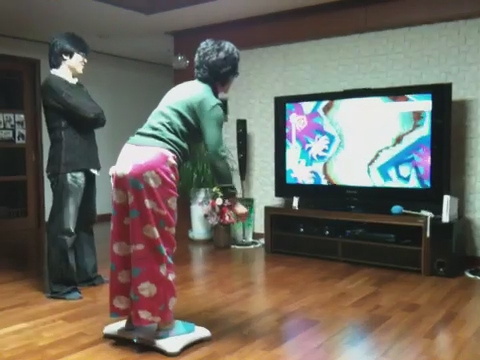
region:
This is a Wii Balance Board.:
[99, 307, 218, 357]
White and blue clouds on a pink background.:
[144, 221, 176, 263]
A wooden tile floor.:
[276, 297, 411, 347]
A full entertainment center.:
[260, 201, 443, 275]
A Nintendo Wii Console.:
[440, 192, 459, 225]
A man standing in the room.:
[36, 24, 107, 305]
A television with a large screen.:
[268, 88, 456, 207]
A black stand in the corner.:
[228, 118, 258, 188]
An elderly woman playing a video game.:
[94, 28, 255, 357]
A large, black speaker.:
[430, 214, 458, 275]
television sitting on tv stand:
[267, 75, 457, 308]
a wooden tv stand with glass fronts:
[265, 199, 433, 271]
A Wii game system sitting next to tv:
[414, 181, 464, 233]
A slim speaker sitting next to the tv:
[232, 112, 262, 227]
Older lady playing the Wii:
[105, 35, 253, 353]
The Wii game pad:
[81, 309, 217, 359]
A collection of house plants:
[195, 160, 264, 270]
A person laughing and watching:
[39, 36, 103, 321]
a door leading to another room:
[1, 48, 44, 242]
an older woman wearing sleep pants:
[100, 137, 193, 345]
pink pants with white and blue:
[105, 141, 181, 324]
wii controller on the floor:
[100, 317, 215, 358]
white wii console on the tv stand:
[439, 190, 460, 224]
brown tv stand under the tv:
[260, 202, 455, 272]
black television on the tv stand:
[271, 82, 454, 206]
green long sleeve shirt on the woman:
[126, 77, 240, 197]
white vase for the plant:
[184, 186, 220, 242]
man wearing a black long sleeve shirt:
[41, 68, 108, 172]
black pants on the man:
[43, 168, 99, 289]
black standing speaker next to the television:
[233, 116, 252, 247]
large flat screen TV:
[273, 81, 451, 197]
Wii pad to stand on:
[103, 304, 210, 354]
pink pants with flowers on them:
[111, 144, 178, 320]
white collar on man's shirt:
[50, 68, 78, 84]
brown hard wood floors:
[1, 219, 478, 356]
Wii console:
[441, 194, 458, 223]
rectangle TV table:
[264, 205, 452, 273]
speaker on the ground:
[434, 251, 467, 276]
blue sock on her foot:
[155, 323, 192, 335]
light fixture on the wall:
[170, 53, 188, 69]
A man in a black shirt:
[29, 26, 107, 300]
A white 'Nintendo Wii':
[433, 186, 457, 219]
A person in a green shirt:
[96, 24, 265, 336]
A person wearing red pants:
[97, 25, 252, 325]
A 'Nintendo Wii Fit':
[85, 303, 216, 351]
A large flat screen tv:
[264, 72, 448, 192]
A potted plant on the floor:
[196, 187, 238, 247]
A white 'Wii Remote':
[414, 205, 429, 233]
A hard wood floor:
[0, 205, 479, 353]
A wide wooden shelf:
[250, 197, 454, 275]